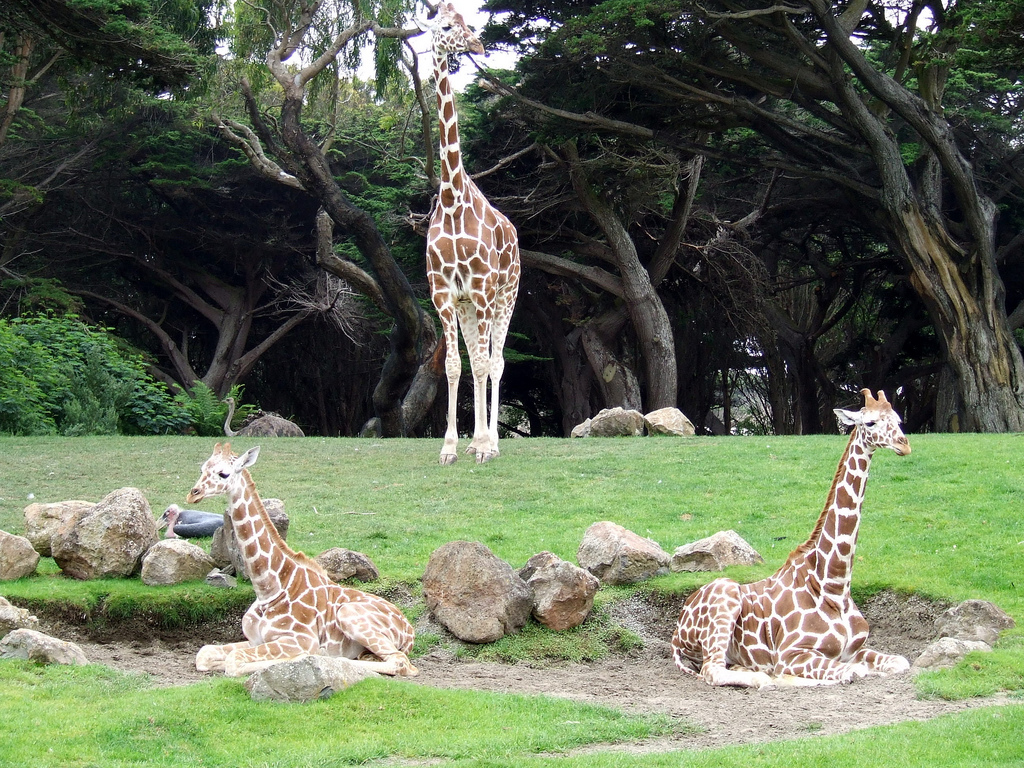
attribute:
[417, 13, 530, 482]
giraffe — tall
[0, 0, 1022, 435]
woods — thick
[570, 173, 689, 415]
branch — curved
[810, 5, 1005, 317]
branch — curved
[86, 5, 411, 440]
branch — curved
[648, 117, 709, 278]
branch — curved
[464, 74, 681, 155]
branch — curved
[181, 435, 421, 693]
giraffe — yellow, brown, white, spotted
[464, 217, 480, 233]
spot — brown spot 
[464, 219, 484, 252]
spot — brown spot 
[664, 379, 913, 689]
giraffe — spotted, brown, white